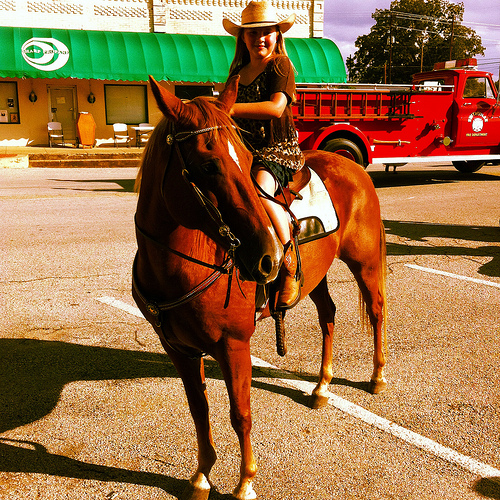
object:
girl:
[221, 2, 306, 310]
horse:
[133, 75, 389, 499]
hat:
[223, 2, 295, 35]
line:
[406, 261, 498, 289]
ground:
[4, 167, 135, 499]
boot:
[278, 238, 306, 312]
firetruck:
[295, 59, 499, 178]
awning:
[2, 29, 350, 85]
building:
[1, 1, 349, 133]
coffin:
[75, 113, 100, 147]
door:
[50, 84, 78, 145]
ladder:
[298, 86, 415, 121]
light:
[433, 59, 478, 68]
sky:
[322, 2, 372, 37]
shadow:
[1, 339, 100, 481]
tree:
[346, 1, 485, 84]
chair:
[47, 122, 64, 145]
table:
[131, 124, 159, 132]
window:
[103, 82, 148, 124]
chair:
[112, 123, 129, 145]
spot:
[227, 139, 243, 171]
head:
[150, 75, 287, 284]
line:
[328, 393, 499, 480]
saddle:
[282, 161, 313, 207]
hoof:
[184, 479, 215, 500]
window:
[0, 80, 21, 125]